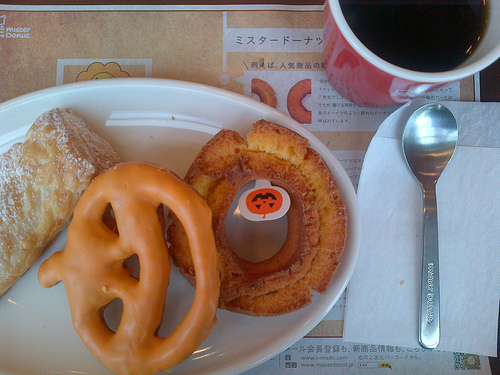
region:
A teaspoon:
[407, 114, 468, 359]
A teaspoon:
[401, 230, 491, 351]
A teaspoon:
[381, 271, 442, 369]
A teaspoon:
[385, 234, 445, 339]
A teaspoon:
[395, 255, 463, 360]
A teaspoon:
[402, 184, 472, 288]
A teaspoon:
[388, 128, 430, 308]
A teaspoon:
[428, 117, 460, 298]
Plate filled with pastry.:
[6, 68, 374, 372]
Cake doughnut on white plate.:
[177, 124, 355, 320]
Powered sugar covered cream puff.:
[4, 123, 114, 293]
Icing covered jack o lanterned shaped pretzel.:
[34, 169, 219, 372]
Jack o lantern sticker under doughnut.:
[228, 181, 293, 222]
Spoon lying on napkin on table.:
[391, 100, 466, 352]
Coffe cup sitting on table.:
[297, 2, 497, 116]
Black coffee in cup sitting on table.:
[362, 5, 499, 79]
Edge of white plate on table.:
[219, 318, 336, 374]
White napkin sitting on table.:
[341, 133, 401, 354]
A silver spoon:
[400, 92, 461, 346]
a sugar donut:
[291, 142, 351, 308]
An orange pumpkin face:
[240, 179, 289, 229]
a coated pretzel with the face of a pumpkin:
[35, 157, 223, 370]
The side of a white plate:
[113, 73, 209, 152]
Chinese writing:
[243, 27, 318, 73]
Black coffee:
[366, 9, 479, 49]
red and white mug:
[327, 43, 395, 118]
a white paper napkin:
[467, 105, 492, 359]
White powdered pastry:
[2, 104, 127, 167]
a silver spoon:
[392, 98, 467, 353]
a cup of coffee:
[315, 0, 499, 105]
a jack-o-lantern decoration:
[237, 182, 294, 224]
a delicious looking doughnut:
[179, 120, 350, 310]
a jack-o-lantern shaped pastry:
[44, 159, 221, 372]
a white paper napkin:
[352, 90, 497, 358]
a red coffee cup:
[313, 1, 479, 110]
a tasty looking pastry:
[4, 108, 109, 255]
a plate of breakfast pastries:
[8, 75, 362, 366]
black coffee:
[339, 0, 490, 65]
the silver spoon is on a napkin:
[402, 102, 457, 349]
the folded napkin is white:
[346, 100, 497, 357]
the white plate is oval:
[1, 76, 360, 373]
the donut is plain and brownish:
[169, 120, 346, 317]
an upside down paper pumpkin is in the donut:
[238, 167, 293, 224]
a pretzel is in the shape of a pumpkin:
[37, 162, 225, 372]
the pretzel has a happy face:
[41, 162, 221, 367]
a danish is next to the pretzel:
[1, 104, 118, 304]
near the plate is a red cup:
[318, 3, 498, 110]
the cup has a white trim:
[318, 3, 499, 111]